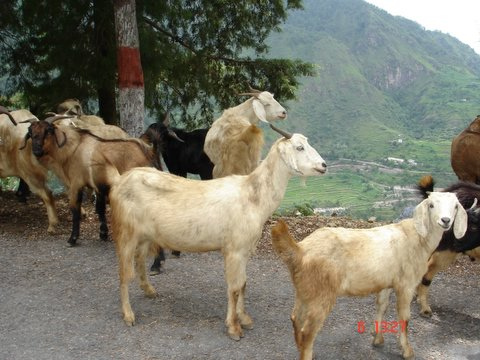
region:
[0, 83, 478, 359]
A group of goats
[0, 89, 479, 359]
The goats on a path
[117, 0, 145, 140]
The red marked beam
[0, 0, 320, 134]
The tree on the left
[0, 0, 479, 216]
The hills in the background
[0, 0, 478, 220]
The green vegetation on the hills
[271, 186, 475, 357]
The white billy on the right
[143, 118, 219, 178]
The dark blocked goat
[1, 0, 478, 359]
The curious looking goats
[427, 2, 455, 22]
this is the sky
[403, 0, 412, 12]
the sky has clouds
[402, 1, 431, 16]
the clouds are white in color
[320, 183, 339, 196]
the grass is green in color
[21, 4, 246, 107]
this is a tree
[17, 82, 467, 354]
these are some goats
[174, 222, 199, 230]
the fur is white in color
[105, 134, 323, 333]
the sheep is white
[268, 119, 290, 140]
the horns are grey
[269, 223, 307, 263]
the tail is brown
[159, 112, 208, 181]
the goat is black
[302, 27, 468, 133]
the hill is in the background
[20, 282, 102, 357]
the floor is grey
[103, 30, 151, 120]
the tree is red and brown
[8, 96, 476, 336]
the goats are nine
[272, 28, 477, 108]
the hill is green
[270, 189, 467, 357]
a light brown goat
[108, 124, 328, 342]
a light brown goat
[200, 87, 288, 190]
a light brown goat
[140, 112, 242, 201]
a black colored goat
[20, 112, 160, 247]
a light brown goat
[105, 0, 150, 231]
a tree with a red marking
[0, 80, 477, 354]
a group of different colored goats standing around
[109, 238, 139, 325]
the leg of a goat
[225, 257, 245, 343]
the leg of a goat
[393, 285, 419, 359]
the leg of a goat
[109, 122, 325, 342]
goat is standing around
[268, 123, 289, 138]
horn of a goat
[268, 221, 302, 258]
the tail is brown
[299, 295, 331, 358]
leg of a goat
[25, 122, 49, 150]
dark hair on head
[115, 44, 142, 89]
brown paint on tree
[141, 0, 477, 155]
mountain in the background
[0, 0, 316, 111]
green pine tree needles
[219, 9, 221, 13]
A green leaf on a plant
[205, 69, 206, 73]
A green leaf on a plant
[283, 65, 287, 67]
A green leaf on a plant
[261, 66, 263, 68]
A green leaf on a plant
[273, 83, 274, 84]
A green leaf on a plant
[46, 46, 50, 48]
A green leaf on a plant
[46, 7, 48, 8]
A green leaf on a plant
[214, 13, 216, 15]
A green leaf on a plant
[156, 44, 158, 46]
A green leaf on a plant